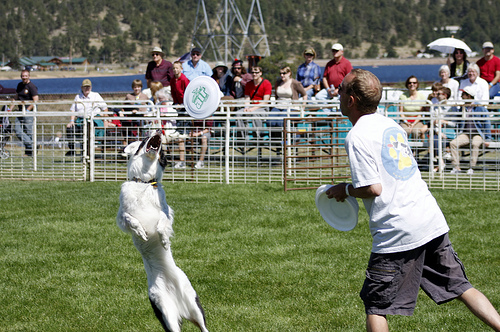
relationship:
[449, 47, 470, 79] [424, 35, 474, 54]
woman holds umbrella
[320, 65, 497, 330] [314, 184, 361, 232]
man playing white frisbees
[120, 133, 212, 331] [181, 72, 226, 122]
dog ready to catch frisbee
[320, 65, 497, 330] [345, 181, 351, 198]
man wearing band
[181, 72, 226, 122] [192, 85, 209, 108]
frisbee with print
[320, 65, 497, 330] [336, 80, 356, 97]
man has sunglasses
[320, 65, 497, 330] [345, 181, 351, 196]
man wearing band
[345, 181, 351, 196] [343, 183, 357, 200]
band around wrist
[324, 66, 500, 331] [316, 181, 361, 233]
man holding frisbees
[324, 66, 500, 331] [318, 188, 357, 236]
man holding frisbee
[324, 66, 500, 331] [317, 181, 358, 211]
man holding frisbee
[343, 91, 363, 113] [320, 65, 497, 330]
ear of man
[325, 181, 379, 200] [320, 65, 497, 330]
hand of man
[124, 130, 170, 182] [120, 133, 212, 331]
head of dog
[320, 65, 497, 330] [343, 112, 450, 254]
man wearing shirt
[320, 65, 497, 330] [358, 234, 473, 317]
man wearing cargo shorts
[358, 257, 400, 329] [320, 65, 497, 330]
leg of man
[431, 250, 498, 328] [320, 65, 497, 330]
leg of man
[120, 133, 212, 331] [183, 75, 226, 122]
dog leaping after frisbee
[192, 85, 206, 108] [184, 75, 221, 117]
print on frisbee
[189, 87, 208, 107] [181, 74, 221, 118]
text on frisbee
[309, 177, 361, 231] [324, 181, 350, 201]
white frisbees in hand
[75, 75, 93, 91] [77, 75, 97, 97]
hat on head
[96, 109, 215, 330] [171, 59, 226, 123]
dog jumping to catch frisbee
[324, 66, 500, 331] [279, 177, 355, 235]
man holding frisbee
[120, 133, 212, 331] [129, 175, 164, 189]
dog wearing collar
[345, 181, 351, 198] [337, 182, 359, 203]
band on wrist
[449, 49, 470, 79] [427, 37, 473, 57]
woman holding umbrella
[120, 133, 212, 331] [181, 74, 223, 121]
dog and frisbee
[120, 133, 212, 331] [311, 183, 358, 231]
dog and frisbee